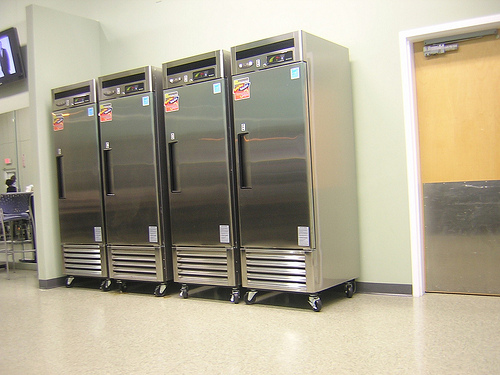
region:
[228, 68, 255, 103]
red picture on fridge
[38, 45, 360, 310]
the fridges are silver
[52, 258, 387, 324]
the fridges have wheels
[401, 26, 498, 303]
door made of wood and metal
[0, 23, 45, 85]
tv mounted on the wall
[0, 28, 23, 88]
the tv is turned on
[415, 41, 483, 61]
metal piece on door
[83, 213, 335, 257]
white labels on fridges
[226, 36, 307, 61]
black panel on top of fridge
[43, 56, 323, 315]
fridge doors are closed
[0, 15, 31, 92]
TV in the corner.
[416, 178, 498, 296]
Bottom of the door is silver.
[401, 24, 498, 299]
The door frame is white.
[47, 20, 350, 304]
There are four refrigerators.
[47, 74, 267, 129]
Stickers on the refrigerators.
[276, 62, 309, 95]
Logos on the refrigerators.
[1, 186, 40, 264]
Chair in the corner.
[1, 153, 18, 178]
Exit sign above a door.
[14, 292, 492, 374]
The floor is beige.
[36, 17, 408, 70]
The wall is white.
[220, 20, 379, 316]
a four wheel container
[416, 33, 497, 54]
latch of a door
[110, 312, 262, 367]
a clear tile flooring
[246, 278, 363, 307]
four wheels of a fridge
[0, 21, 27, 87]
television set mounted on wall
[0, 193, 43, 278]
chair on the floor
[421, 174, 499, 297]
sheet of metal mounted on door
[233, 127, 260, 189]
handles of a fridge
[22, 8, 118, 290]
small section of wall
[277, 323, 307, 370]
reflections from the light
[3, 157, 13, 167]
exit sign on wall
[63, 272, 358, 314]
wheels on bottom of machines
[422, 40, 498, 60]
hydraulic hinge on door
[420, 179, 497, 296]
stainless steel kick plate on door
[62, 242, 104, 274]
air vent on bottom of machine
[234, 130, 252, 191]
handle on door of machine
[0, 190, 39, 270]
blue printed chair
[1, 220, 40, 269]
metal legs on chair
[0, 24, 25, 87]
television on wall of room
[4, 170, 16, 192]
people standing in doorway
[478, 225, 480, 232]
part of a door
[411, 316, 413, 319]
part of a floor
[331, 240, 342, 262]
part of a shelf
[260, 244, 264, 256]
part of a door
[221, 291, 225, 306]
side of a floor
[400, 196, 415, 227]
edge of a door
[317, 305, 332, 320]
part of a wheel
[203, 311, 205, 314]
edge of a floor